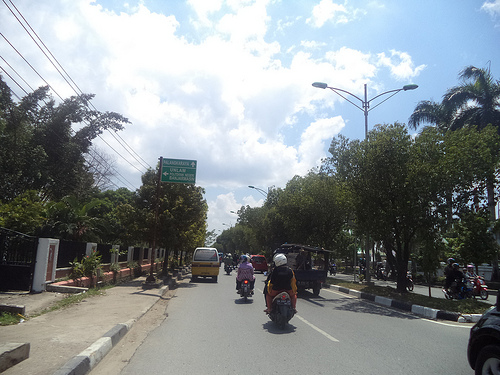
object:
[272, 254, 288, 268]
helmet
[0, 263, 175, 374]
pavement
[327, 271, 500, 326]
sidewalk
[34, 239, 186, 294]
retaining wall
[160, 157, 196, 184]
sign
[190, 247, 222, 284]
vehicle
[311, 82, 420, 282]
streetlamp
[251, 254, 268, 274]
car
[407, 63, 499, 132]
foliage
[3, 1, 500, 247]
sky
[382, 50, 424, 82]
cloud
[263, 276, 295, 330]
motorcycle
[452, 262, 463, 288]
person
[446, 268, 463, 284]
shirt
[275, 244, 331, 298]
truck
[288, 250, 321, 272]
items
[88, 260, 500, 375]
road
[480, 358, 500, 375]
wheel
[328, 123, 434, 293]
tree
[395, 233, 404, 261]
stem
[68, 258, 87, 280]
plant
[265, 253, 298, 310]
man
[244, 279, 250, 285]
rear light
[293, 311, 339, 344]
strip